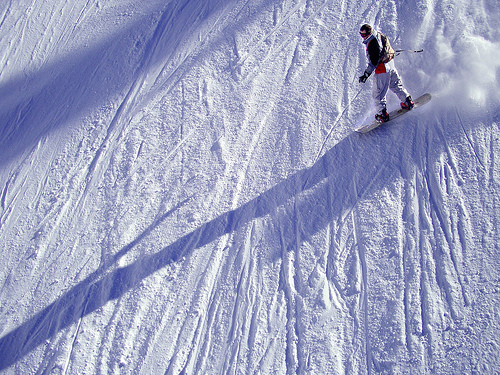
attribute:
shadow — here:
[0, 108, 418, 374]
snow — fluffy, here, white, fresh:
[1, 2, 499, 375]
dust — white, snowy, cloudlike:
[416, 34, 500, 125]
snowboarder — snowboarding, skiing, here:
[358, 22, 414, 123]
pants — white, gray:
[374, 67, 413, 117]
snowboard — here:
[354, 93, 432, 135]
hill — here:
[1, 1, 499, 374]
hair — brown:
[359, 23, 373, 35]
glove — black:
[358, 75, 366, 83]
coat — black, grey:
[362, 31, 397, 75]